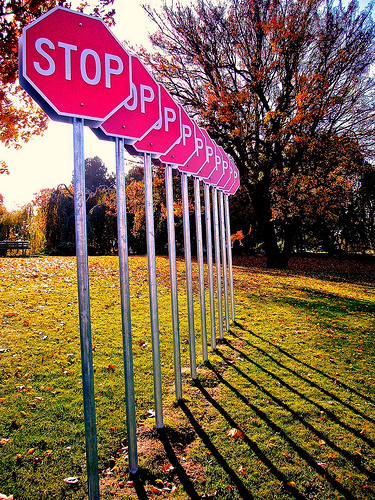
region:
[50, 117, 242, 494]
tall silver poles buried in the ground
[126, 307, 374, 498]
shadows of tall poles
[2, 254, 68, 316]
autumn leaves on a patch of grass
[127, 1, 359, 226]
tall tree with autumn foliage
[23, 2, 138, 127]
red stop sign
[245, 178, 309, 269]
dark trunk on a tall tree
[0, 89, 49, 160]
sun shining through autumn leaves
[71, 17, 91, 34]
single bolt in the stop sign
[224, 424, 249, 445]
single fallen leaf on the ground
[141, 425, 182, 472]
disturbed earth at foot of stop sign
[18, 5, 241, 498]
ten traffic STOP signs in ground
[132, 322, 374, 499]
shadow from STOP sign poles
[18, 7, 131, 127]
octagon red and white stop sign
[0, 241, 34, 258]
wooden park bench in distance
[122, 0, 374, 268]
large tree with yellow and orange leaves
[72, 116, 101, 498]
metal pole holding up STOP sign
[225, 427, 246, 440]
orange leaf on park ground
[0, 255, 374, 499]
green grassy area at park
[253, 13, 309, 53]
thick patch of leaves on tree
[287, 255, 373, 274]
pile of leaves under tree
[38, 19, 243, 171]
stop signs in row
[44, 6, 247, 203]
signs are red and white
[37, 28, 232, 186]
stop signs are octagonal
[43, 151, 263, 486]
stop signs on poles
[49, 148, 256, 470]
row of poles are metallic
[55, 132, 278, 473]
row of poles are grey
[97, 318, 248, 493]
brown dirt under poles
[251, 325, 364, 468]
green grass next to poles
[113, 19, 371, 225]
tall tree behind poles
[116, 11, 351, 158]
tree has orange leaves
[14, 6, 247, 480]
a row of a stop signs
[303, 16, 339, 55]
branches of a tree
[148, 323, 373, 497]
shadows on the ground of poles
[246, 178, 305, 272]
the trunk of a tree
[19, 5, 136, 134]
the word "STOP" on a sign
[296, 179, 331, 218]
the leaves on a tree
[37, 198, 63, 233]
the leaves on a tree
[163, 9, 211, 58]
the branches of a tree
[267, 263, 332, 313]
shadows of trees on the ground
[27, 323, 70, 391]
the green grass of a lawn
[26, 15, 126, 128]
a red stop sign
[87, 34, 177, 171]
a red stop sign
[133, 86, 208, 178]
a red stop sign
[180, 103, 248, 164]
a red stop sign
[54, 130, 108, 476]
the pole is gray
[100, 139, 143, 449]
the pole is gray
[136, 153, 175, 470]
the pole is gray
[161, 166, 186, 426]
the pole is gray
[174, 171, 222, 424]
the pole is gray